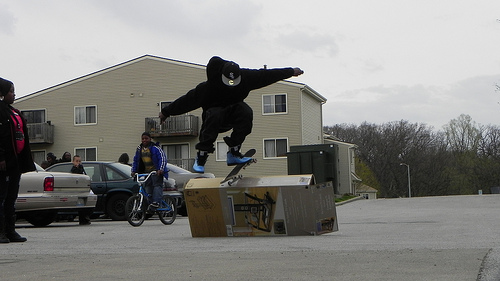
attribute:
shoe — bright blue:
[225, 146, 252, 166]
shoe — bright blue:
[191, 149, 211, 172]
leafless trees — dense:
[326, 115, 492, 198]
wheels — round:
[121, 195, 178, 227]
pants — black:
[0, 147, 26, 228]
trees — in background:
[434, 111, 495, 196]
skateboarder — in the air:
[153, 55, 303, 172]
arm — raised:
[244, 67, 304, 85]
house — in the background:
[40, 32, 417, 247]